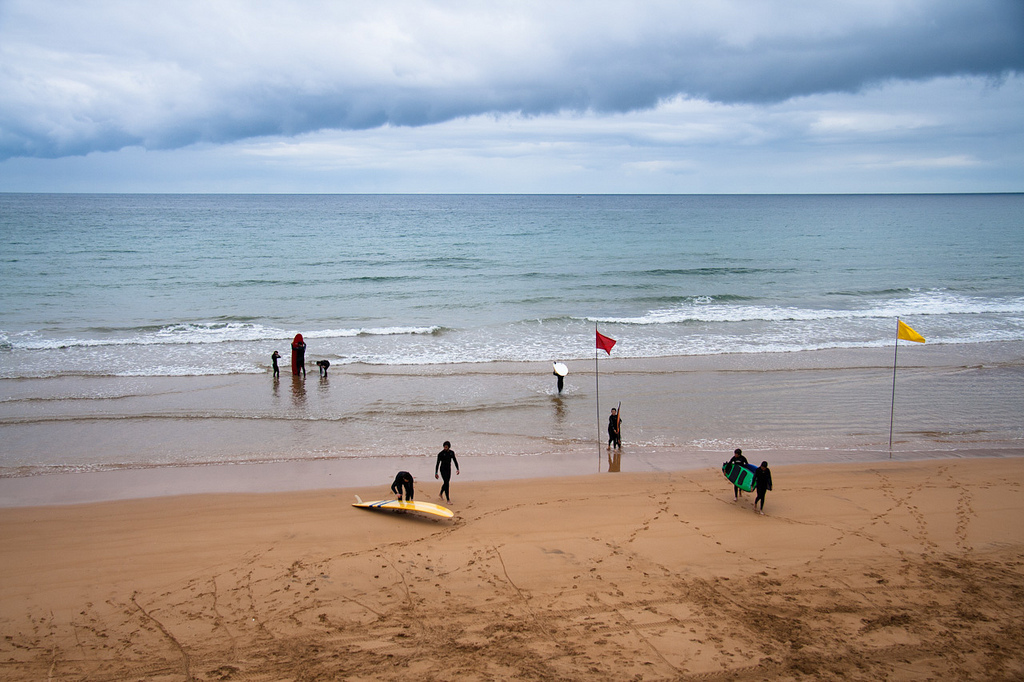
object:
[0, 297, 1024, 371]
waves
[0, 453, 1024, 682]
sand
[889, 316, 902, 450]
pole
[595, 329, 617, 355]
flag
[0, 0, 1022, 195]
clouds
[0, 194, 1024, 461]
water